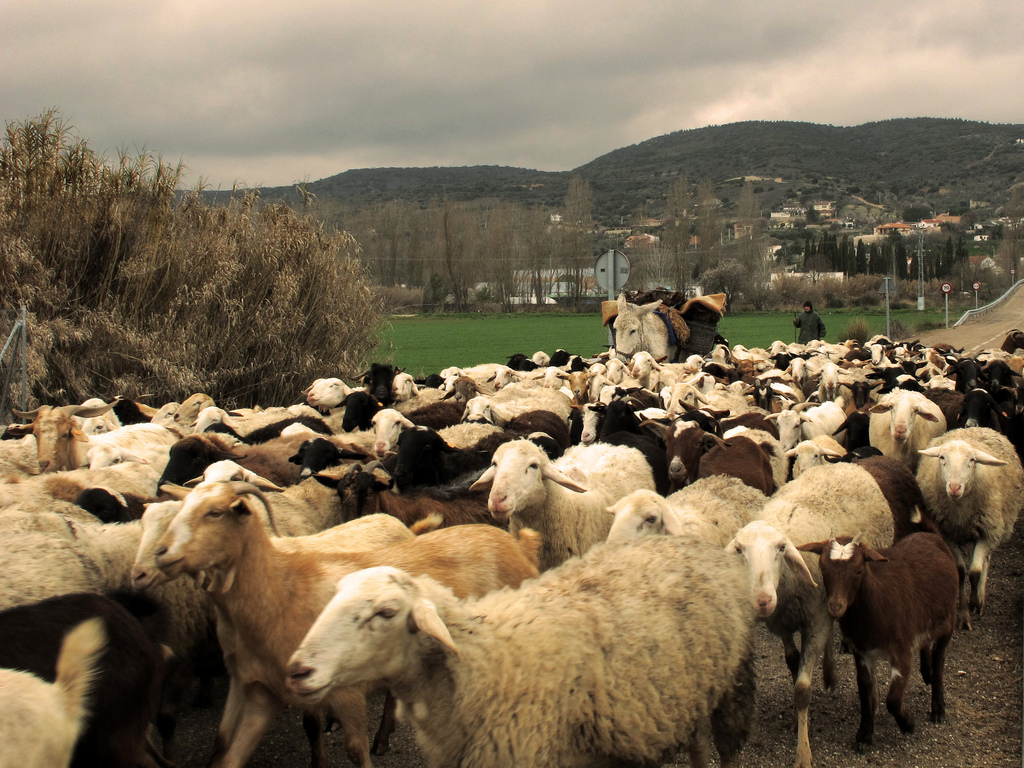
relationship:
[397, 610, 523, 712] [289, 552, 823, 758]
ear of sheep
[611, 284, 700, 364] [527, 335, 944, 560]
horse behind sheep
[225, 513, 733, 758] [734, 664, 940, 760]
sheep on road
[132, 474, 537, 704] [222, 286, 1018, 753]
sheep in field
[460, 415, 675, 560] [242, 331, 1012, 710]
sheep in field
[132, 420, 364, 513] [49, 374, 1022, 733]
sheep in field